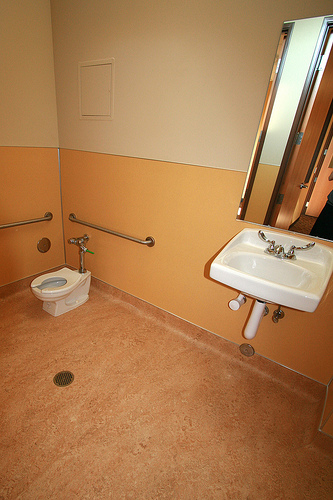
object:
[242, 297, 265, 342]
pipe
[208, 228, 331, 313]
sink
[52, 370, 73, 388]
drain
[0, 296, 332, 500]
floor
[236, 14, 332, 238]
mirror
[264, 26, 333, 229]
door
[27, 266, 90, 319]
toilet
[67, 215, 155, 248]
railing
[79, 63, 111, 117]
door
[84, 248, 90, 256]
flush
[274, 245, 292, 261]
faucet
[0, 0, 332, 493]
bathroom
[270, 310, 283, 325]
valve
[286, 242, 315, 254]
handles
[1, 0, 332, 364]
wall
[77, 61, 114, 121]
panel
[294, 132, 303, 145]
hinge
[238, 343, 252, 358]
orb